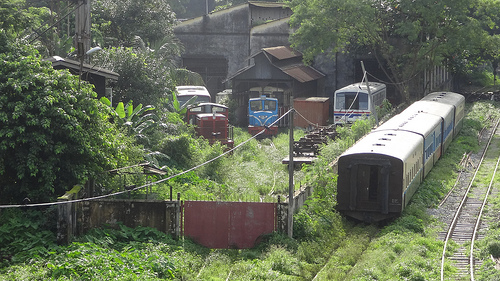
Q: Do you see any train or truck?
A: Yes, there is a train.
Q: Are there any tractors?
A: No, there are no tractors.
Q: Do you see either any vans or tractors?
A: No, there are no tractors or vans.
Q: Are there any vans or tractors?
A: No, there are no tractors or vans.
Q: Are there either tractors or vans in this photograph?
A: No, there are no tractors or vans.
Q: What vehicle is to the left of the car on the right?
A: The vehicle is a train.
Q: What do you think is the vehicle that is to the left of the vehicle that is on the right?
A: The vehicle is a train.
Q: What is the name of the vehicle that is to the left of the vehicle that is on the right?
A: The vehicle is a train.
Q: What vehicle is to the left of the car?
A: The vehicle is a train.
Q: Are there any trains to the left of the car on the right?
A: Yes, there is a train to the left of the car.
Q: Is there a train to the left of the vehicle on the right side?
A: Yes, there is a train to the left of the car.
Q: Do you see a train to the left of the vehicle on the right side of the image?
A: Yes, there is a train to the left of the car.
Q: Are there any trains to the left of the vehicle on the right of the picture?
A: Yes, there is a train to the left of the car.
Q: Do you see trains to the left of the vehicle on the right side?
A: Yes, there is a train to the left of the car.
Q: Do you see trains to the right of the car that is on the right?
A: No, the train is to the left of the car.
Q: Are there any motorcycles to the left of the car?
A: No, there is a train to the left of the car.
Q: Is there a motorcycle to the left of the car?
A: No, there is a train to the left of the car.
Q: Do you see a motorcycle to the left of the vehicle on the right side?
A: No, there is a train to the left of the car.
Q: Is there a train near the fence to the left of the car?
A: Yes, there is a train near the fence.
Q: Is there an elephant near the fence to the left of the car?
A: No, there is a train near the fence.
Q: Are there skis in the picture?
A: No, there are no skis.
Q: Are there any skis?
A: No, there are no skis.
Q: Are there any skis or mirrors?
A: No, there are no skis or mirrors.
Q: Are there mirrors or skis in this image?
A: No, there are no skis or mirrors.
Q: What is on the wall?
A: The moss is on the wall.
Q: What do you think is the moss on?
A: The moss is on the wall.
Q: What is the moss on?
A: The moss is on the wall.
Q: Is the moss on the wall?
A: Yes, the moss is on the wall.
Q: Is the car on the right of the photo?
A: Yes, the car is on the right of the image.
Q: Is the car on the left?
A: No, the car is on the right of the image.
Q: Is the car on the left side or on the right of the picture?
A: The car is on the right of the image.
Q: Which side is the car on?
A: The car is on the right of the image.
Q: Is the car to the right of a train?
A: Yes, the car is to the right of a train.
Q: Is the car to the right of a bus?
A: No, the car is to the right of a train.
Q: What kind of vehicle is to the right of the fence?
A: The vehicle is a car.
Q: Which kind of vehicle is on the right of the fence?
A: The vehicle is a car.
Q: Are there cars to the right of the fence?
A: Yes, there is a car to the right of the fence.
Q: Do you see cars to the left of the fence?
A: No, the car is to the right of the fence.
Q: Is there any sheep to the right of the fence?
A: No, there is a car to the right of the fence.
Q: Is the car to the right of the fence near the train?
A: Yes, the car is to the right of the fence.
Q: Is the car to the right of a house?
A: No, the car is to the right of the fence.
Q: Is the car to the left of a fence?
A: No, the car is to the right of a fence.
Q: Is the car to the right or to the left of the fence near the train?
A: The car is to the right of the fence.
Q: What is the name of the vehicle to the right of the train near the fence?
A: The vehicle is a car.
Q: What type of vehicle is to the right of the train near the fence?
A: The vehicle is a car.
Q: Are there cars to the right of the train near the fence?
A: Yes, there is a car to the right of the train.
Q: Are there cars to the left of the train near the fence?
A: No, the car is to the right of the train.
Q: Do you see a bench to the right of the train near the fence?
A: No, there is a car to the right of the train.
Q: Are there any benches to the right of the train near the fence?
A: No, there is a car to the right of the train.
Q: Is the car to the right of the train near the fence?
A: Yes, the car is to the right of the train.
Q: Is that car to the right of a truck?
A: No, the car is to the right of the train.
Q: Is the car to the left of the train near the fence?
A: No, the car is to the right of the train.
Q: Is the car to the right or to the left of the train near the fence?
A: The car is to the right of the train.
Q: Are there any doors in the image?
A: Yes, there is a door.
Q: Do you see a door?
A: Yes, there is a door.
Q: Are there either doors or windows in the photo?
A: Yes, there is a door.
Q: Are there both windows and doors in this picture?
A: Yes, there are both a door and windows.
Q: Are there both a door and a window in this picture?
A: Yes, there are both a door and a window.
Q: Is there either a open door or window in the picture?
A: Yes, there is an open door.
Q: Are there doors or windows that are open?
A: Yes, the door is open.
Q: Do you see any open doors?
A: Yes, there is an open door.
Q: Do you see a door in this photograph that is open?
A: Yes, there is an open door.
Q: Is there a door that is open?
A: Yes, there is a door that is open.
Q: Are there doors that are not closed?
A: Yes, there is a open door.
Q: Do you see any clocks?
A: No, there are no clocks.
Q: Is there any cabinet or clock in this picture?
A: No, there are no clocks or cabinets.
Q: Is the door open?
A: Yes, the door is open.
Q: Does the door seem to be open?
A: Yes, the door is open.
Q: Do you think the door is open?
A: Yes, the door is open.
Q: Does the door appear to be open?
A: Yes, the door is open.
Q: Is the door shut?
A: No, the door is open.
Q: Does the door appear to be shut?
A: No, the door is open.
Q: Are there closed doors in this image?
A: No, there is a door but it is open.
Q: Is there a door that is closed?
A: No, there is a door but it is open.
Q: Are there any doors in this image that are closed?
A: No, there is a door but it is open.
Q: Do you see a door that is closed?
A: No, there is a door but it is open.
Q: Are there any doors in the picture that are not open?
A: No, there is a door but it is open.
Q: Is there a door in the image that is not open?
A: No, there is a door but it is open.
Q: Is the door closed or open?
A: The door is open.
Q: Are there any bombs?
A: No, there are no bombs.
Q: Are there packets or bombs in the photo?
A: No, there are no bombs or packets.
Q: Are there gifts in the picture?
A: No, there are no gifts.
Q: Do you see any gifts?
A: No, there are no gifts.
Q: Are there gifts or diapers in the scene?
A: No, there are no gifts or diapers.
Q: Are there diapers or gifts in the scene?
A: No, there are no gifts or diapers.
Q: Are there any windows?
A: Yes, there is a window.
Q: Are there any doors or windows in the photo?
A: Yes, there is a window.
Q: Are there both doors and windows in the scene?
A: Yes, there are both a window and a door.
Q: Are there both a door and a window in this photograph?
A: Yes, there are both a window and a door.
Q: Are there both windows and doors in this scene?
A: Yes, there are both a window and a door.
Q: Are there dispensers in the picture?
A: No, there are no dispensers.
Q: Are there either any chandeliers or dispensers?
A: No, there are no dispensers or chandeliers.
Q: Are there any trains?
A: Yes, there is a train.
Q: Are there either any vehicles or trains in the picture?
A: Yes, there is a train.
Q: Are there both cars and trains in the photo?
A: Yes, there are both a train and a car.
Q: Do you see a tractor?
A: No, there are no tractors.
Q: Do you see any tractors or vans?
A: No, there are no tractors or vans.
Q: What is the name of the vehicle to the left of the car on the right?
A: The vehicle is a train.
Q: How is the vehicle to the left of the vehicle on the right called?
A: The vehicle is a train.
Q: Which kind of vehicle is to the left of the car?
A: The vehicle is a train.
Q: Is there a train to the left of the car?
A: Yes, there is a train to the left of the car.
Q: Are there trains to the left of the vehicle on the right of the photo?
A: Yes, there is a train to the left of the car.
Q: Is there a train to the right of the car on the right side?
A: No, the train is to the left of the car.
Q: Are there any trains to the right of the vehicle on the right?
A: No, the train is to the left of the car.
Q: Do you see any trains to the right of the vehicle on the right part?
A: No, the train is to the left of the car.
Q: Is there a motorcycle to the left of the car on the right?
A: No, there is a train to the left of the car.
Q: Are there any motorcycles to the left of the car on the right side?
A: No, there is a train to the left of the car.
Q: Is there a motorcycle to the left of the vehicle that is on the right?
A: No, there is a train to the left of the car.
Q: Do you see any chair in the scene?
A: No, there are no chairs.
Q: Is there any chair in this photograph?
A: No, there are no chairs.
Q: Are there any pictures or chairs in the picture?
A: No, there are no chairs or pictures.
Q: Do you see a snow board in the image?
A: No, there are no snowboards.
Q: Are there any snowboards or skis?
A: No, there are no snowboards or skis.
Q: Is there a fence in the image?
A: Yes, there is a fence.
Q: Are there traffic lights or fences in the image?
A: Yes, there is a fence.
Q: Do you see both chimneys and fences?
A: No, there is a fence but no chimneys.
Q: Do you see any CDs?
A: No, there are no cds.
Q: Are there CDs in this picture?
A: No, there are no cds.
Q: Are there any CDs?
A: No, there are no cds.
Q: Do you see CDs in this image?
A: No, there are no cds.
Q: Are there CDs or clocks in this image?
A: No, there are no CDs or clocks.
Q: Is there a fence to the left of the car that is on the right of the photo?
A: Yes, there is a fence to the left of the car.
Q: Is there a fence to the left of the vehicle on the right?
A: Yes, there is a fence to the left of the car.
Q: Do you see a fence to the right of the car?
A: No, the fence is to the left of the car.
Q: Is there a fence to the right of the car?
A: No, the fence is to the left of the car.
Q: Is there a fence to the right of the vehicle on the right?
A: No, the fence is to the left of the car.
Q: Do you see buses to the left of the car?
A: No, there is a fence to the left of the car.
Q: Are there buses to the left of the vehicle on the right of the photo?
A: No, there is a fence to the left of the car.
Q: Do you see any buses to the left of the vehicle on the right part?
A: No, there is a fence to the left of the car.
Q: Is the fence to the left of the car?
A: Yes, the fence is to the left of the car.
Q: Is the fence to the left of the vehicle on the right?
A: Yes, the fence is to the left of the car.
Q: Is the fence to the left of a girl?
A: No, the fence is to the left of the car.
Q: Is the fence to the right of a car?
A: No, the fence is to the left of a car.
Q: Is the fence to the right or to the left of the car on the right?
A: The fence is to the left of the car.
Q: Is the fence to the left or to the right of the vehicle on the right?
A: The fence is to the left of the car.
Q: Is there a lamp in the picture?
A: No, there are no lamps.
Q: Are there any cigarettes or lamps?
A: No, there are no lamps or cigarettes.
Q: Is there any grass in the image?
A: Yes, there is grass.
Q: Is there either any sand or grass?
A: Yes, there is grass.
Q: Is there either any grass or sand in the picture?
A: Yes, there is grass.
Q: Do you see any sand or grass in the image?
A: Yes, there is grass.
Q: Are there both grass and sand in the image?
A: No, there is grass but no sand.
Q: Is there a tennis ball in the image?
A: No, there are no tennis balls.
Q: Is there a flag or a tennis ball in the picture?
A: No, there are no tennis balls or flags.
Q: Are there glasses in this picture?
A: No, there are no glasses.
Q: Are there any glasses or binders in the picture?
A: No, there are no glasses or binders.